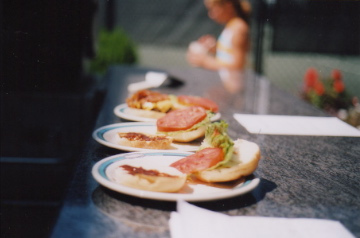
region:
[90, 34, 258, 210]
food on the counter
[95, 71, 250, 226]
three plates of sandwiches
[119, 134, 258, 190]
burguer in first plate on the counter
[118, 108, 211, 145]
burguer in middle plate on the counter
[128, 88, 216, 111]
burguer in third plate on the counter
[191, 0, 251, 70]
kid wearing white t-shirt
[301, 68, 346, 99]
orange flowers on the corner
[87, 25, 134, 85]
small green bush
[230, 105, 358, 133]
white paper on the counter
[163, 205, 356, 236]
bunch of papers on the counter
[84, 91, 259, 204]
three white plates on the counter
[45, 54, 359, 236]
large gray counter on house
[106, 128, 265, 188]
burguer open in first plate in the counter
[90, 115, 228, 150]
burguer open in middle plate in the counter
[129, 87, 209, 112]
burguer open in third plate in the counter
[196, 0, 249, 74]
kid standing next to the counter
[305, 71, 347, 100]
orange flowers in the corner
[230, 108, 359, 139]
white paper on counter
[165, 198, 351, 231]
bunch of white papers on the counter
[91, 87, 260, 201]
Lunch is served...I think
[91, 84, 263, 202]
Where's the beef?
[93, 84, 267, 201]
What does a meatless sandwich look like?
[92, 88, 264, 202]
three tomatoes in search of a sandwich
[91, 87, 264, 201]
Nothing...it's what's for dinner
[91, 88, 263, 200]
What does a boring sandwich look like?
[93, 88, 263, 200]
Weight Watchers be damned...where's the beef?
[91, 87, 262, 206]
This is why diets suck!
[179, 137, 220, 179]
Red tomato on the plate.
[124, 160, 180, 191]
Burnt piece of bread on plate.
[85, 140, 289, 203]
Blue and white plate.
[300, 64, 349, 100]
Orange flowers in the back.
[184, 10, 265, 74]
Girl walking across the back.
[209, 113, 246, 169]
Piece of lettuce on bread.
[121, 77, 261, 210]
Three plates on the counter.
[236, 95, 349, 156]
White piece of paper.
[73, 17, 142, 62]
Small green plant in the corner.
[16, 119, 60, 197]
Black in the background.